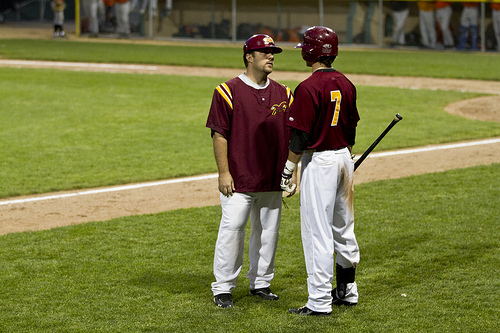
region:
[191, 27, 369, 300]
these are two baseball players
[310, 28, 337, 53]
this is a helmet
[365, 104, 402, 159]
this is a bat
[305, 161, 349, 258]
this is the trousers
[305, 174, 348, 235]
the trouser is white in color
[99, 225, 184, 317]
this is the grass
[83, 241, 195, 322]
the grass is short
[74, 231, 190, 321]
the grass is green in color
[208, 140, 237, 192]
this is the hand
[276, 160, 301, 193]
this is a glove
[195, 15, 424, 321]
baseball players on a field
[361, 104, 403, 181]
baseball bat in player's hands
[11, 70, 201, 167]
green grass of a field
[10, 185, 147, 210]
white line painted on field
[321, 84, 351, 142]
number on player's jersey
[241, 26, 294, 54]
baseball cap on a coach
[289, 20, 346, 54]
helmet on baseball player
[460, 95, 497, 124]
dirt ground on a field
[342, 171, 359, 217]
dirt stain on white pants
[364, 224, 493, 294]
shadow casted on the ground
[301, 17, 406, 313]
man wearing a helmet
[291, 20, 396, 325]
man wearing maroon shirt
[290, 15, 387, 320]
man wearing white pants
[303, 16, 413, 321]
man holding a bat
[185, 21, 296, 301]
man wearing a cap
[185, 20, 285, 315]
man wearing white pants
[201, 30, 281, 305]
man wearing maroon shirt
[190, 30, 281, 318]
man wearing black shoes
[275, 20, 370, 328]
man wearing white gloves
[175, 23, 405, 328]
men standing on field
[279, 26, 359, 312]
A man in uniform with the number 7 on his back.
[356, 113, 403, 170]
A black bat.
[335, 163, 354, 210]
Dirty spot on the back of white pants.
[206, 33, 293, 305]
A man in a maroon shirt talking to numer 7.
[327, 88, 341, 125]
A yellow number 7.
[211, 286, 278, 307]
Black cleats on the guy talking to number 7.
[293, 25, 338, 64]
Maroon helmet on number 7.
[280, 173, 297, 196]
White and black glove on the left hand of number 7.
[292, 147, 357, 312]
Dirty white pants of number 7.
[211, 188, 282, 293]
White pants of a guy talking to number 7.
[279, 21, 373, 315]
player with dirt on white pants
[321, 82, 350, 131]
7 on back of maroon jersey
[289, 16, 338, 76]
maroon helmet on player's head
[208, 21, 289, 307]
player talking to another man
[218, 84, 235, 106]
yellow stripe on jersey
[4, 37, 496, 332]
green baseball field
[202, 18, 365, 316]
two baseball players talking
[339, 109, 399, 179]
black baseball bat in hand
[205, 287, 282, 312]
player has on black and white cleats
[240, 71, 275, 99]
white t-shirt under jersey